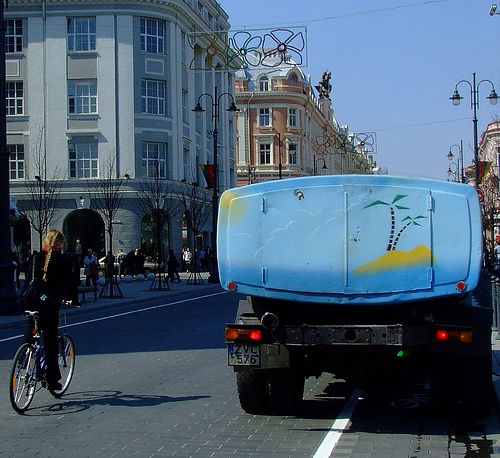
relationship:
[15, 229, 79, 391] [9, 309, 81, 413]
girl on a bike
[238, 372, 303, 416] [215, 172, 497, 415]
wheels on a truck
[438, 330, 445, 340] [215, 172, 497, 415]
tail light of a truck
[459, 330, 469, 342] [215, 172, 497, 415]
tail light of a truck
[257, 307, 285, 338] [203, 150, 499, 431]
exhaust on a truck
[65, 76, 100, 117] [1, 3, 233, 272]
window on building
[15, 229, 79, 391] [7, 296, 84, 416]
girl riding bike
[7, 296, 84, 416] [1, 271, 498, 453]
bike on street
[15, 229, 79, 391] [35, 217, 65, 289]
girl has hair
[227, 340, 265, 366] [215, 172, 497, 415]
tag on truck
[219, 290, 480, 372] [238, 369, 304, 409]
truck has tires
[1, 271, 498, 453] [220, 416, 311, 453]
street has pavers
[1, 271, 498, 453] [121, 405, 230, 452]
street has pavers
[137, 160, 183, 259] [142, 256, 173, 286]
tree in cage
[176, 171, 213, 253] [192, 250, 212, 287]
tree in cage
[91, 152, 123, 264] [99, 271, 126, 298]
tree in cage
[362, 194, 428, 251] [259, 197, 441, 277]
palm tree on sign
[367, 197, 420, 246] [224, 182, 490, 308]
palm tree on truck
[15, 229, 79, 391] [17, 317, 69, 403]
girl on bike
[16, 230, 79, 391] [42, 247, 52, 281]
girl has braid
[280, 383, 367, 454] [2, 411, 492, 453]
line on road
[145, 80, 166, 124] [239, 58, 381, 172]
window on building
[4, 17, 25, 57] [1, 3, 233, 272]
window on building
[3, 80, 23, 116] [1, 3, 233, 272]
white window on building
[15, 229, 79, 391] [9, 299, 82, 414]
girl on bike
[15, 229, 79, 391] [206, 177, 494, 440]
girl rides past truck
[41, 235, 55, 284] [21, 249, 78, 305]
braid on coat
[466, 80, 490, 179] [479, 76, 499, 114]
street light with lamp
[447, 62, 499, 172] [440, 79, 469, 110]
cake with lamp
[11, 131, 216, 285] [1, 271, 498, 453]
trees along street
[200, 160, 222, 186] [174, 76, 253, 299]
banner on post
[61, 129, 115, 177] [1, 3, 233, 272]
window on building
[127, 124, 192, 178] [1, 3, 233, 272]
window on building